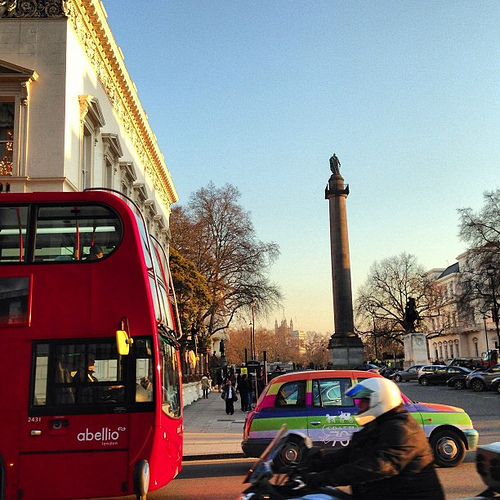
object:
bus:
[0, 187, 182, 499]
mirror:
[116, 328, 131, 354]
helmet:
[345, 376, 400, 429]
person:
[305, 375, 446, 498]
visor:
[348, 385, 370, 412]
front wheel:
[432, 427, 466, 467]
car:
[241, 369, 478, 467]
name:
[321, 409, 355, 446]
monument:
[323, 154, 365, 368]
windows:
[79, 96, 170, 272]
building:
[0, 0, 177, 405]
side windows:
[276, 377, 368, 408]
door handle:
[312, 420, 322, 428]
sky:
[100, 1, 499, 334]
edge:
[130, 197, 169, 497]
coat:
[307, 411, 450, 499]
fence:
[184, 373, 216, 409]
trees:
[357, 190, 499, 363]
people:
[217, 364, 259, 414]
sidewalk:
[183, 379, 248, 437]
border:
[64, 0, 179, 213]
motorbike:
[237, 422, 348, 499]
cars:
[394, 363, 497, 391]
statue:
[398, 297, 420, 333]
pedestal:
[401, 333, 434, 372]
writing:
[77, 426, 128, 447]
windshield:
[244, 425, 288, 486]